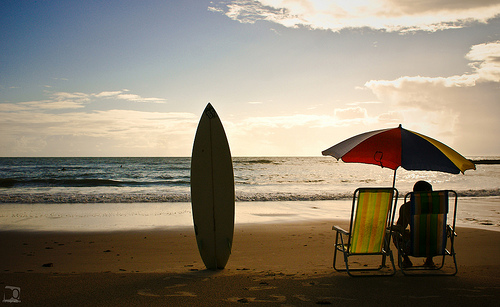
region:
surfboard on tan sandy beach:
[183, 100, 249, 267]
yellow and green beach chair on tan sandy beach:
[328, 179, 388, 268]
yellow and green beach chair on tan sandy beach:
[394, 188, 462, 270]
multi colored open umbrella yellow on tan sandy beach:
[308, 116, 474, 180]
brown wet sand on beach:
[15, 199, 175, 281]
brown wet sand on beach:
[254, 203, 324, 283]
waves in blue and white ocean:
[19, 159, 170, 196]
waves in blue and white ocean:
[245, 156, 325, 204]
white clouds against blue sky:
[6, 6, 168, 147]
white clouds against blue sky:
[172, 11, 477, 101]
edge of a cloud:
[314, 17, 358, 41]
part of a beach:
[158, 242, 185, 266]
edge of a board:
[213, 187, 242, 242]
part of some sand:
[271, 229, 302, 269]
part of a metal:
[333, 245, 360, 271]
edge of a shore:
[256, 202, 294, 229]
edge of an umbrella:
[356, 136, 405, 189]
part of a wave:
[113, 170, 148, 206]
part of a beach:
[263, 256, 298, 301]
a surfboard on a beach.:
[178, 99, 257, 284]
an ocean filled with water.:
[1, 156, 498, 202]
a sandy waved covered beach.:
[4, 196, 499, 301]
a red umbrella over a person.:
[316, 121, 476, 256]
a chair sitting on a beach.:
[315, 180, 400, 265]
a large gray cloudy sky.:
[347, 37, 494, 147]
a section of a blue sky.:
[3, 1, 498, 101]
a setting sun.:
[270, 97, 375, 162]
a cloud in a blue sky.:
[88, 70, 179, 108]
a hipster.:
[376, 156, 467, 285]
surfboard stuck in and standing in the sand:
[188, 98, 238, 281]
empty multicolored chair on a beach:
[328, 183, 398, 278]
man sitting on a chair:
[387, 179, 466, 274]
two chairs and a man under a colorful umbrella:
[318, 123, 476, 275]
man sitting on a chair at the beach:
[393, 175, 463, 271]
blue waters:
[1, 153, 498, 198]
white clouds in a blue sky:
[204, 1, 496, 79]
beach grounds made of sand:
[6, 194, 499, 301]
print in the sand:
[179, 258, 201, 280]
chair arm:
[329, 223, 349, 237]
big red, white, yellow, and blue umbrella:
[314, 116, 481, 181]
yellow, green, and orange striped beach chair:
[325, 181, 395, 286]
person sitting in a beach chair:
[387, 177, 470, 282]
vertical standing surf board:
[176, 91, 245, 278]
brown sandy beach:
[1, 202, 498, 304]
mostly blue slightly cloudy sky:
[0, 0, 499, 162]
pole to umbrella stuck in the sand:
[379, 163, 399, 270]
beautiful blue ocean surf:
[1, 149, 498, 199]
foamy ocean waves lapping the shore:
[2, 187, 498, 204]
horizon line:
[0, 150, 499, 165]